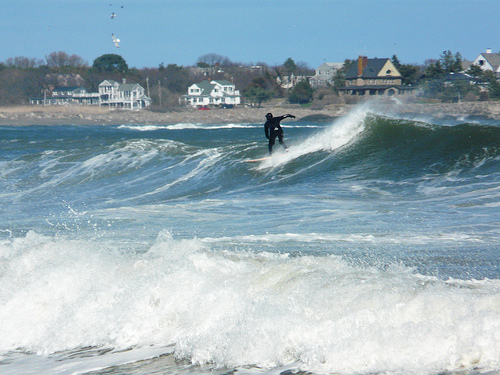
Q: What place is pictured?
A: It is an ocean.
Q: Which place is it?
A: It is an ocean.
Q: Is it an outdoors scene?
A: Yes, it is outdoors.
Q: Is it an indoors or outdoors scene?
A: It is outdoors.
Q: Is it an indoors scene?
A: No, it is outdoors.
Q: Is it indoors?
A: No, it is outdoors.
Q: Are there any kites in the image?
A: No, there are no kites.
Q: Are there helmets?
A: No, there are no helmets.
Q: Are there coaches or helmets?
A: No, there are no helmets or coaches.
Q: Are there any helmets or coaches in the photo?
A: No, there are no helmets or coaches.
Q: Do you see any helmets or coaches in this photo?
A: No, there are no helmets or coaches.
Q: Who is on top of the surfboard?
A: The man is on top of the surfboard.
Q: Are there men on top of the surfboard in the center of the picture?
A: Yes, there is a man on top of the surfboard.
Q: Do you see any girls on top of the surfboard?
A: No, there is a man on top of the surfboard.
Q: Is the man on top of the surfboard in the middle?
A: Yes, the man is on top of the surfboard.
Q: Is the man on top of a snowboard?
A: No, the man is on top of the surfboard.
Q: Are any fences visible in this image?
A: No, there are no fences.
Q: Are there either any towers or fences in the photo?
A: No, there are no fences or towers.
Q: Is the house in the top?
A: Yes, the house is in the top of the image.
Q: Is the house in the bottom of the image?
A: No, the house is in the top of the image.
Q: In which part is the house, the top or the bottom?
A: The house is in the top of the image.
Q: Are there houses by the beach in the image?
A: Yes, there is a house by the beach.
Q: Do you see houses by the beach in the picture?
A: Yes, there is a house by the beach.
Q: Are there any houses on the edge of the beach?
A: Yes, there is a house on the edge of the beach.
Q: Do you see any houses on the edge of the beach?
A: Yes, there is a house on the edge of the beach.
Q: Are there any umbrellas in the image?
A: No, there are no umbrellas.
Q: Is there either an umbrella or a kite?
A: No, there are no umbrellas or kites.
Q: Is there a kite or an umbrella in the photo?
A: No, there are no umbrellas or kites.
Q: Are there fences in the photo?
A: No, there are no fences.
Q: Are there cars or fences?
A: No, there are no fences or cars.